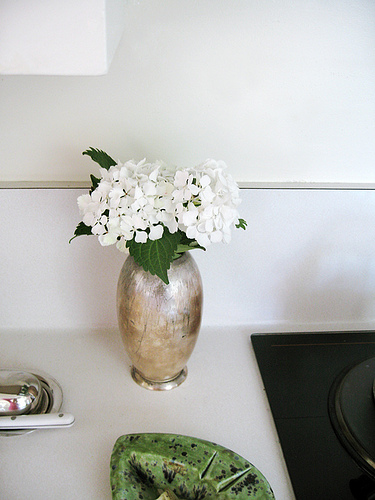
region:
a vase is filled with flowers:
[74, 142, 247, 406]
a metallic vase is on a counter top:
[77, 148, 237, 404]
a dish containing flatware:
[1, 365, 84, 431]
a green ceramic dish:
[105, 424, 285, 498]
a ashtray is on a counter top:
[104, 426, 285, 498]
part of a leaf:
[129, 231, 175, 284]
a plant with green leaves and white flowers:
[79, 148, 239, 277]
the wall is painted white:
[140, 7, 323, 152]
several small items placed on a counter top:
[0, 107, 301, 498]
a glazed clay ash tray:
[87, 427, 286, 498]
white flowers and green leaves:
[60, 120, 256, 270]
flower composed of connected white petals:
[69, 160, 189, 245]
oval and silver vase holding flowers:
[71, 150, 246, 395]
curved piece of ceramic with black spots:
[90, 411, 272, 489]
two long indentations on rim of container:
[175, 439, 265, 490]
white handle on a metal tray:
[3, 400, 78, 433]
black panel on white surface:
[225, 326, 349, 486]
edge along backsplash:
[33, 171, 350, 194]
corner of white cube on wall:
[33, 15, 142, 100]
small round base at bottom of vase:
[108, 360, 202, 390]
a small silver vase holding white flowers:
[42, 135, 274, 396]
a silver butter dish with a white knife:
[4, 356, 79, 448]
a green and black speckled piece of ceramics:
[100, 433, 280, 498]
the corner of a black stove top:
[254, 331, 374, 495]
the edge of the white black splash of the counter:
[246, 170, 371, 203]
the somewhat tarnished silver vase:
[117, 257, 216, 393]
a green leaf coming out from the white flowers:
[122, 228, 192, 285]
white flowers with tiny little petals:
[176, 168, 235, 238]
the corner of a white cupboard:
[2, 3, 131, 95]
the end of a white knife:
[2, 410, 84, 437]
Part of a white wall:
[136, 0, 371, 155]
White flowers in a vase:
[66, 144, 250, 392]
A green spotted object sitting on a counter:
[104, 430, 277, 498]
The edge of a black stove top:
[248, 332, 373, 498]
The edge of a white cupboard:
[0, 0, 106, 77]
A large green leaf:
[127, 240, 173, 285]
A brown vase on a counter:
[114, 257, 209, 389]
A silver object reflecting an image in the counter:
[0, 371, 62, 414]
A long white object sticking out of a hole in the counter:
[0, 410, 77, 429]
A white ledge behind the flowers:
[0, 174, 373, 200]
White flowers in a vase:
[60, 139, 252, 259]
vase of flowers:
[106, 251, 209, 402]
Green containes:
[102, 423, 287, 499]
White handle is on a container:
[0, 405, 82, 435]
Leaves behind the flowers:
[128, 240, 184, 287]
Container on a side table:
[0, 362, 73, 445]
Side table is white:
[3, 316, 298, 497]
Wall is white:
[3, 0, 371, 170]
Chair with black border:
[317, 335, 372, 481]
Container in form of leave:
[94, 418, 285, 498]